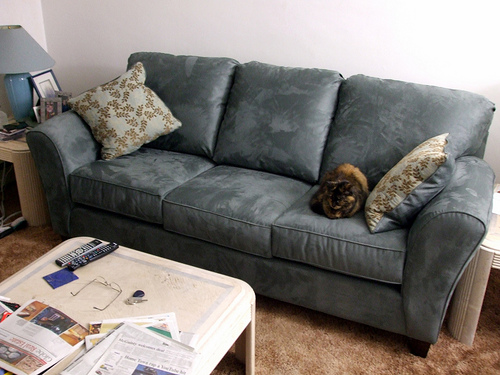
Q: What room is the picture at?
A: It is at the living room.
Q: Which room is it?
A: It is a living room.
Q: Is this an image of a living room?
A: Yes, it is showing a living room.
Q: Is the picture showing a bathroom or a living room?
A: It is showing a living room.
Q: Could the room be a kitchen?
A: No, it is a living room.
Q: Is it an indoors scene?
A: Yes, it is indoors.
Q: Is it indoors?
A: Yes, it is indoors.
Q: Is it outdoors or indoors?
A: It is indoors.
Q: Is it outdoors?
A: No, it is indoors.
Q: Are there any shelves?
A: No, there are no shelves.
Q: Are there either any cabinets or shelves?
A: No, there are no shelves or cabinets.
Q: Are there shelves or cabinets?
A: No, there are no shelves or cabinets.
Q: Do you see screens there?
A: No, there are no screens.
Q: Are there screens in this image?
A: No, there are no screens.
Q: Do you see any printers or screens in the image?
A: No, there are no screens or printers.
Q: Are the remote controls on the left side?
A: Yes, the remote controls are on the left of the image.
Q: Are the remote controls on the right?
A: No, the remote controls are on the left of the image.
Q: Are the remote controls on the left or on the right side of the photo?
A: The remote controls are on the left of the image.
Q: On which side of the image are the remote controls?
A: The remote controls are on the left of the image.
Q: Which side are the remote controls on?
A: The remote controls are on the left of the image.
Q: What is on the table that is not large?
A: The remote controls are on the table.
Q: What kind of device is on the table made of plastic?
A: The devices are remote controls.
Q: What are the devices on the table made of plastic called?
A: The devices are remote controls.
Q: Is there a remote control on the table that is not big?
A: Yes, there are remote controls on the table.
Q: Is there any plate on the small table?
A: No, there are remote controls on the table.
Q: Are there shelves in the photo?
A: No, there are no shelves.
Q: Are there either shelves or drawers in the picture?
A: No, there are no shelves or drawers.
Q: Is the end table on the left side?
A: Yes, the end table is on the left of the image.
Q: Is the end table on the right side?
A: No, the end table is on the left of the image.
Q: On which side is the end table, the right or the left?
A: The end table is on the left of the image.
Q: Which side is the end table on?
A: The end table is on the left of the image.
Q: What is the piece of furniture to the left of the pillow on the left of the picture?
A: The piece of furniture is an end table.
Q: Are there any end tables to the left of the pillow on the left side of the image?
A: Yes, there is an end table to the left of the pillow.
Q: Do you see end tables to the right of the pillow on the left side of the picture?
A: No, the end table is to the left of the pillow.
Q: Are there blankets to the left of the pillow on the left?
A: No, there is an end table to the left of the pillow.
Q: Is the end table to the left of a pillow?
A: Yes, the end table is to the left of a pillow.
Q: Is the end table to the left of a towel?
A: No, the end table is to the left of a pillow.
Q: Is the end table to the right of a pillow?
A: No, the end table is to the left of a pillow.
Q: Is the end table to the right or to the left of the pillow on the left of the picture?
A: The end table is to the left of the pillow.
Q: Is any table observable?
A: Yes, there is a table.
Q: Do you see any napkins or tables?
A: Yes, there is a table.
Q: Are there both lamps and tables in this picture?
A: Yes, there are both a table and a lamp.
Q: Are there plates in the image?
A: No, there are no plates.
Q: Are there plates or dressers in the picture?
A: No, there are no plates or dressers.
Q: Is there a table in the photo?
A: Yes, there is a table.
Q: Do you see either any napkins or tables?
A: Yes, there is a table.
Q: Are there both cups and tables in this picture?
A: No, there is a table but no cups.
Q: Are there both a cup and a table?
A: No, there is a table but no cups.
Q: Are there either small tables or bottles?
A: Yes, there is a small table.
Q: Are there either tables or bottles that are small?
A: Yes, the table is small.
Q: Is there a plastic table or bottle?
A: Yes, there is a plastic table.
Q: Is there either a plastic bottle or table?
A: Yes, there is a plastic table.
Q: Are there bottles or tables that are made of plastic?
A: Yes, the table is made of plastic.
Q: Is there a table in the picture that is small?
A: Yes, there is a table that is small.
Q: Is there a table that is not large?
A: Yes, there is a small table.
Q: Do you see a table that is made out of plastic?
A: Yes, there is a table that is made of plastic.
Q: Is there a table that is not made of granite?
A: Yes, there is a table that is made of plastic.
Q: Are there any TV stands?
A: No, there are no TV stands.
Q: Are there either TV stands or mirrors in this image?
A: No, there are no TV stands or mirrors.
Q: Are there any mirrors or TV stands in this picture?
A: No, there are no TV stands or mirrors.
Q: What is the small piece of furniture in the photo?
A: The piece of furniture is a table.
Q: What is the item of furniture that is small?
A: The piece of furniture is a table.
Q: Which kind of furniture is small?
A: The furniture is a table.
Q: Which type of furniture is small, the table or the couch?
A: The table is small.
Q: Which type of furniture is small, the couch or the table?
A: The table is small.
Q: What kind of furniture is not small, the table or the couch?
A: The couch is not small.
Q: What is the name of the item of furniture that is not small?
A: The piece of furniture is a couch.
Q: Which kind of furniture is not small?
A: The furniture is a couch.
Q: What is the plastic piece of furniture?
A: The piece of furniture is a table.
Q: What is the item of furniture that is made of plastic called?
A: The piece of furniture is a table.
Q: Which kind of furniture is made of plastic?
A: The furniture is a table.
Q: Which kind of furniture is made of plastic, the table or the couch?
A: The table is made of plastic.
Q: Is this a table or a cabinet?
A: This is a table.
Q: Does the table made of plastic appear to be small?
A: Yes, the table is small.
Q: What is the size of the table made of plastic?
A: The table is small.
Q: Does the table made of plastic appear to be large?
A: No, the table is small.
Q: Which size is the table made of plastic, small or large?
A: The table is small.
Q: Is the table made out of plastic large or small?
A: The table is small.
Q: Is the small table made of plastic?
A: Yes, the table is made of plastic.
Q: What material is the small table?
A: The table is made of plastic.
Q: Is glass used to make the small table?
A: No, the table is made of plastic.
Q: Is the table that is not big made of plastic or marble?
A: The table is made of plastic.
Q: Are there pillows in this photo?
A: Yes, there is a pillow.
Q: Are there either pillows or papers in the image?
A: Yes, there is a pillow.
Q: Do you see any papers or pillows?
A: Yes, there is a pillow.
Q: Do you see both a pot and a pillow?
A: No, there is a pillow but no pots.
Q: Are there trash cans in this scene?
A: No, there are no trash cans.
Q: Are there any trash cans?
A: No, there are no trash cans.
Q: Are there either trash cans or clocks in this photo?
A: No, there are no trash cans or clocks.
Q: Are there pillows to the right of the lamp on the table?
A: Yes, there is a pillow to the right of the lamp.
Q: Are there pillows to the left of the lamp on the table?
A: No, the pillow is to the right of the lamp.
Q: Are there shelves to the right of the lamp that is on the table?
A: No, there is a pillow to the right of the lamp.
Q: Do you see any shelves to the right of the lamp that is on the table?
A: No, there is a pillow to the right of the lamp.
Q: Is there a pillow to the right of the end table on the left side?
A: Yes, there is a pillow to the right of the end table.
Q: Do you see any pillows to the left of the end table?
A: No, the pillow is to the right of the end table.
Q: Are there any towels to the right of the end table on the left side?
A: No, there is a pillow to the right of the end table.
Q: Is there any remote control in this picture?
A: Yes, there is a remote control.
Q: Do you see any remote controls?
A: Yes, there is a remote control.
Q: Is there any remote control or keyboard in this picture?
A: Yes, there is a remote control.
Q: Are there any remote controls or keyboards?
A: Yes, there is a remote control.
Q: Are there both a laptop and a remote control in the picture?
A: No, there is a remote control but no laptops.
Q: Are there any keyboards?
A: No, there are no keyboards.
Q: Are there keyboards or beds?
A: No, there are no keyboards or beds.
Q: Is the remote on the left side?
A: Yes, the remote is on the left of the image.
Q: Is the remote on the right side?
A: No, the remote is on the left of the image.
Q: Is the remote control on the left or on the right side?
A: The remote control is on the left of the image.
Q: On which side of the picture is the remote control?
A: The remote control is on the left of the image.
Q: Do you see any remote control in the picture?
A: Yes, there is a remote control.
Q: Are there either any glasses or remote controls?
A: Yes, there is a remote control.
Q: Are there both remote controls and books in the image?
A: No, there is a remote control but no books.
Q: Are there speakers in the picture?
A: No, there are no speakers.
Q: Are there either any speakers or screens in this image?
A: No, there are no speakers or screens.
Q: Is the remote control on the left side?
A: Yes, the remote control is on the left of the image.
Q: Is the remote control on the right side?
A: No, the remote control is on the left of the image.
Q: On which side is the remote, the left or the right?
A: The remote is on the left of the image.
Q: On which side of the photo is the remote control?
A: The remote control is on the left of the image.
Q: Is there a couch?
A: Yes, there is a couch.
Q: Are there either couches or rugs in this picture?
A: Yes, there is a couch.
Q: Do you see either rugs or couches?
A: Yes, there is a couch.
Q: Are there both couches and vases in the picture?
A: No, there is a couch but no vases.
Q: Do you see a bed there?
A: No, there are no beds.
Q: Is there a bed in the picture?
A: No, there are no beds.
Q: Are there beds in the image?
A: No, there are no beds.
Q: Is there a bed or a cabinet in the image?
A: No, there are no beds or cabinets.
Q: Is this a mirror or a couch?
A: This is a couch.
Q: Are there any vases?
A: No, there are no vases.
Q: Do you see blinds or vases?
A: No, there are no vases or blinds.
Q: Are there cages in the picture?
A: No, there are no cages.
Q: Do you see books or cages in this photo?
A: No, there are no cages or books.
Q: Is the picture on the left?
A: Yes, the picture is on the left of the image.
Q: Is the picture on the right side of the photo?
A: No, the picture is on the left of the image.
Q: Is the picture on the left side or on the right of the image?
A: The picture is on the left of the image.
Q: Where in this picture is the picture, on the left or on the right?
A: The picture is on the left of the image.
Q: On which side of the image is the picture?
A: The picture is on the left of the image.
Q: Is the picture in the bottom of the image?
A: No, the picture is in the top of the image.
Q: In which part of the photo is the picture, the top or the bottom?
A: The picture is in the top of the image.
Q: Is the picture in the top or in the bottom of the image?
A: The picture is in the top of the image.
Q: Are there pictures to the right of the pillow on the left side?
A: No, the picture is to the left of the pillow.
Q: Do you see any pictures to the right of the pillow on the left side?
A: No, the picture is to the left of the pillow.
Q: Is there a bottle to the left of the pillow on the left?
A: No, there is a picture to the left of the pillow.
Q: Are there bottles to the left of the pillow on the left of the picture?
A: No, there is a picture to the left of the pillow.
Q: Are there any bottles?
A: No, there are no bottles.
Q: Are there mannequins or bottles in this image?
A: No, there are no bottles or mannequins.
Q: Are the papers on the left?
A: Yes, the papers are on the left of the image.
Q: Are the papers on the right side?
A: No, the papers are on the left of the image.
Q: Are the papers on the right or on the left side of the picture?
A: The papers are on the left of the image.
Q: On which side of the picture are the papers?
A: The papers are on the left of the image.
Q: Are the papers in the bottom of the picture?
A: Yes, the papers are in the bottom of the image.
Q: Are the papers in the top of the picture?
A: No, the papers are in the bottom of the image.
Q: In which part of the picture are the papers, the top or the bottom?
A: The papers are in the bottom of the image.